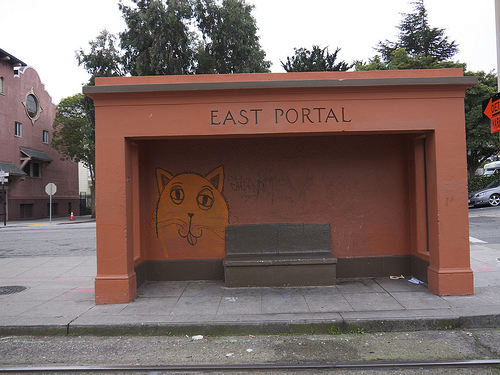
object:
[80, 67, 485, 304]
bus stop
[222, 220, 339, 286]
bench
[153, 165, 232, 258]
cat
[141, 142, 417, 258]
wall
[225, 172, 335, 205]
graffiti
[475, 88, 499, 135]
sign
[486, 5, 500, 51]
post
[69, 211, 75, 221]
cone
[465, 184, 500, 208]
car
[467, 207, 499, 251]
street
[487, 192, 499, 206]
tire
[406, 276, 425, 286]
paper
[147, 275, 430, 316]
ground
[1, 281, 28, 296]
drain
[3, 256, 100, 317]
pavement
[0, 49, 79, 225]
building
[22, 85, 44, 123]
window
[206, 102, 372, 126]
letters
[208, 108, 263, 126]
east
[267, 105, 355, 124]
portal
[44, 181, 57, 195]
back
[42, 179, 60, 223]
sign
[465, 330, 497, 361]
hole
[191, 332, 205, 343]
garbage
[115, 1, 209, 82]
tree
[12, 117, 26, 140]
window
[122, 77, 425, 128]
wall